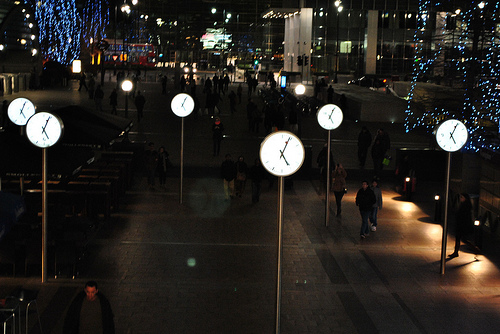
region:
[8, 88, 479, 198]
clocks are seen.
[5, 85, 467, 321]
clocks are attached to the pole.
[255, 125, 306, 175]
clocks are white and black color.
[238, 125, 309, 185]
5.05 is the time shown.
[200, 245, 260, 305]
pathway is grey color.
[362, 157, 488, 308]
light reflection is seen in pathway.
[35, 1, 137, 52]
blue color hanging lights for decoration.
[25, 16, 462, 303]
night time picture.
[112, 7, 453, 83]
lights are on.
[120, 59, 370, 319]
people are walking in the sidewalk.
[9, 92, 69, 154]
white clocks with black numbers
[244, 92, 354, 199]
white clocks with black numbers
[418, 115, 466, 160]
white clock with black numbers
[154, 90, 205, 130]
white clock with black numbers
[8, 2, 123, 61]
blue lights that are lit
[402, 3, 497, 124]
blue lights that are lit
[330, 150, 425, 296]
pedestrians walking on sidewalk at night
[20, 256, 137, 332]
pedestrians walking on sidewalk at night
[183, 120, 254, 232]
pedestrians walking on sidewalk at night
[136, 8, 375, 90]
buildings decorated for holiday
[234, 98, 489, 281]
glowing clocks on poles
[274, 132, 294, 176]
two black hands on clock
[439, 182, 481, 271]
woman walking under clock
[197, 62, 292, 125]
crowd of people in the distance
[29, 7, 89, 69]
blue hanging lights above walkway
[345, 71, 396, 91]
car in front of building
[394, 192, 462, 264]
light reflection on ground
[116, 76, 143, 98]
round light on pole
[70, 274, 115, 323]
man with dark hair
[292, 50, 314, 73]
traffic lights in front of building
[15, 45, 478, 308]
clocks on thin posts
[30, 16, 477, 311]
decorated city street at night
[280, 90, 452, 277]
people walking along street at night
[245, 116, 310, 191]
white clock face with black hands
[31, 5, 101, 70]
small blue lights hanging vertically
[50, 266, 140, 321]
man walking in dark with face illuminated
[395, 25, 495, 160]
tiny blue lights over a lit clock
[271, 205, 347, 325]
edge of brick path in some light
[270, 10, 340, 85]
row of white columns lit from above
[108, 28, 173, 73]
double-decker bus lit from within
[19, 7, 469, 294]
people walking through city at night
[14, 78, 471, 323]
six tall decorative clocks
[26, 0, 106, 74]
blue christmas lights on trees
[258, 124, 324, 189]
clock with white face and black hands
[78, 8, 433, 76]
city buildings lit up at night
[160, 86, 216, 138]
clock shown with time of 5:05pm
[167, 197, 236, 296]
large brick sidewalk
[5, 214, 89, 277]
black table and chairs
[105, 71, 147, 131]
tall round street lights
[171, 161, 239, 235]
reflection of clock on picture